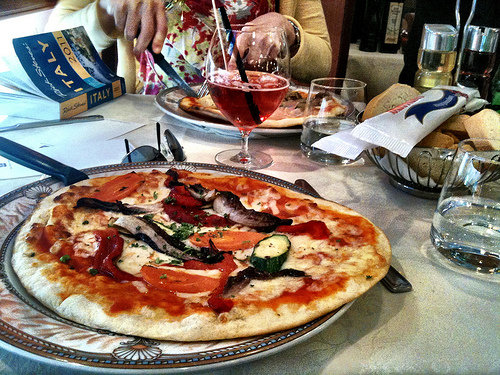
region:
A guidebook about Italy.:
[5, 32, 130, 114]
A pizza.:
[10, 165, 395, 345]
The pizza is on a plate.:
[5, 145, 385, 370]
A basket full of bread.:
[370, 70, 490, 166]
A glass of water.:
[435, 135, 495, 265]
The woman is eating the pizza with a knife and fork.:
[70, 0, 347, 127]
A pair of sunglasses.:
[107, 116, 192, 172]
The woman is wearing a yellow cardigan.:
[45, 1, 325, 93]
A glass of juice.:
[200, 21, 285, 166]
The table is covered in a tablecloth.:
[15, 86, 480, 352]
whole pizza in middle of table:
[20, 125, 413, 341]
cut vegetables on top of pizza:
[41, 180, 306, 295]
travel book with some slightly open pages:
[5, 30, 132, 125]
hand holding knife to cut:
[101, 26, 201, 111]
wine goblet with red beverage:
[185, 20, 300, 171]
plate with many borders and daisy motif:
[21, 310, 283, 360]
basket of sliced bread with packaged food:
[352, 65, 492, 207]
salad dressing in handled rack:
[410, 5, 495, 105]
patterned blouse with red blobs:
[120, 6, 250, 88]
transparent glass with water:
[405, 117, 495, 264]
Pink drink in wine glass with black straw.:
[201, 6, 295, 169]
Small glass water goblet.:
[431, 147, 498, 282]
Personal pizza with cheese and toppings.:
[14, 174, 398, 345]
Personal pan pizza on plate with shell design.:
[0, 143, 443, 373]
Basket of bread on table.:
[366, 69, 498, 191]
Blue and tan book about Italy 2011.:
[0, 21, 132, 132]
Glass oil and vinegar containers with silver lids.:
[416, 17, 499, 100]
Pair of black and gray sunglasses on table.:
[116, 121, 208, 171]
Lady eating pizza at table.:
[2, 3, 496, 365]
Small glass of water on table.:
[298, 69, 372, 183]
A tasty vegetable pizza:
[0, 151, 392, 331]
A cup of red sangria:
[199, 12, 293, 169]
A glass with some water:
[433, 136, 497, 288]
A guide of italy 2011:
[3, 19, 132, 129]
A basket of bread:
[373, 86, 498, 196]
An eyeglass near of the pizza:
[114, 124, 201, 168]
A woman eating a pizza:
[76, 1, 345, 143]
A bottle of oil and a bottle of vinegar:
[418, 22, 498, 104]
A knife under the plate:
[288, 164, 424, 311]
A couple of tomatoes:
[147, 224, 257, 319]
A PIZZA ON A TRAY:
[6, 151, 408, 358]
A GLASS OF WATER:
[429, 125, 496, 284]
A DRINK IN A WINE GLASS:
[194, 40, 299, 175]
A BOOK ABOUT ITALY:
[12, 30, 135, 124]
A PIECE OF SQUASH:
[242, 232, 295, 282]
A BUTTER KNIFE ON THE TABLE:
[289, 178, 417, 296]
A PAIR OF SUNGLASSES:
[107, 118, 192, 168]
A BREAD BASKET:
[351, 74, 496, 199]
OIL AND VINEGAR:
[412, 14, 495, 93]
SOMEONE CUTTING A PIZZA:
[49, 1, 339, 98]